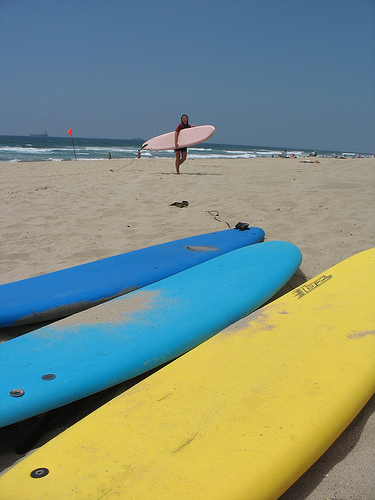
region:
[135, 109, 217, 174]
girl carrying a pink surfboard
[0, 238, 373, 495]
yellow surfboard laying on the beach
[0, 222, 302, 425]
two blue surfboards laying on the beach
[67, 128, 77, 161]
orange flag on top of a stick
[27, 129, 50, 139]
large boat on the horizon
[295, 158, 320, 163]
person laying on the beach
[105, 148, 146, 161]
two people walking in the waves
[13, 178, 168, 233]
brown sand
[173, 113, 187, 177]
surfer on the beach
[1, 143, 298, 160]
waves breaking on the beach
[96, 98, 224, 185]
woman carrying a surfboard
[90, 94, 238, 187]
woman walking away from the water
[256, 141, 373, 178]
people sitting and laying on the beach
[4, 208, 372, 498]
three surfboards laying in the sand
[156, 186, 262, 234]
black surfboard leash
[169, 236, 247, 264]
clump of sand on top of the surfboard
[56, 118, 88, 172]
orange flag blowing in the wind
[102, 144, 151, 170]
two people walking on the beach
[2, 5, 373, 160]
no clouds are in the sky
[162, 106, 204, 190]
woman wearing black and red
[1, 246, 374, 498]
A large plain yellow surfboard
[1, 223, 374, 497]
A row of different-colored surfboards on a beach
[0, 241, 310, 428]
A light bright blue surfboard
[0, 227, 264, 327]
A bright, dark blue surfboard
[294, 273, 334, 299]
A logo on the yellow surfboard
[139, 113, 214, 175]
A surfer walking on the beach with their board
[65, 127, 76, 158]
An orange flag stuck in the sand by the water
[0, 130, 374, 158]
Turbulent sea water with a boat in the distance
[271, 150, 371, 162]
People gathered at the edge of the beach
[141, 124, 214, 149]
A pale pink surfboard held by the surfer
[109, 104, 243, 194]
surf boarder in the beach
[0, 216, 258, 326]
blue surf boards laying on the sand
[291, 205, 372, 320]
yellow surf board laying on the sand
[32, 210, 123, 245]
soft beige dry sand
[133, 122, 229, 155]
pink surf board being carried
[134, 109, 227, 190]
woman posing in the beach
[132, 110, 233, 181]
woman carried surf board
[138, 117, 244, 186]
woman with black and red swimming suit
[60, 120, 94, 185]
red flag on the beach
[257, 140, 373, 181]
people laying on the beach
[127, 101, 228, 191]
woman holding a surf board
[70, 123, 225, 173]
pink surfboard with a black leash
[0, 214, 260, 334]
dark blue surfboard on the beach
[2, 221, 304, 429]
light blue surfboard laying on the beach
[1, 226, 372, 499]
yellow surfboard with "bz" logo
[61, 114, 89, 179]
orange flag stuck in the sand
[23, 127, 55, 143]
boat in the distance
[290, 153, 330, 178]
person laying on the beach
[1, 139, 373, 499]
light brown sandy beach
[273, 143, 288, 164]
person sitting on the beach